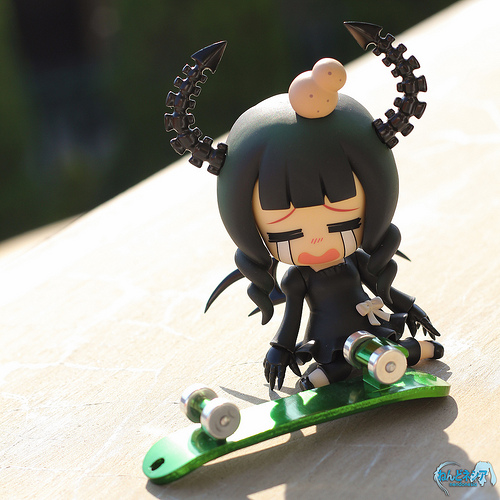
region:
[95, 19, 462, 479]
action figure with a green skateboard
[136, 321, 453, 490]
green skateboard with white wheels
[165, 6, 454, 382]
action figure with black horns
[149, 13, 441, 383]
action figure with black hair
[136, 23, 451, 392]
action figure with sad face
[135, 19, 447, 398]
action figure is crying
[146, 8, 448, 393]
action figure wearing all black with a single white bow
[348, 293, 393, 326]
white bow on action figure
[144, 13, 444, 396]
action figure wearing black gloves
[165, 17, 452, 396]
action figure with black hair and bangs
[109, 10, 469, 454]
plastic figurine on table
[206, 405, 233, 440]
wheel on the skateboard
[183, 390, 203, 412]
wheel on the skateboard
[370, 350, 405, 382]
wheel on the skateboard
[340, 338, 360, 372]
wheel on the skateboard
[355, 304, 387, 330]
bow on the figurine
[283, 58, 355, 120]
knot on the head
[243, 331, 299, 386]
hand of the figurine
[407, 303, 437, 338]
hand of the figurine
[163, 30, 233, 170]
horn of the figurine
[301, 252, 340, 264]
the lips are pink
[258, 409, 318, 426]
the skateboard is green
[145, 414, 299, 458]
the board is upside down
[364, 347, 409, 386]
the wheels are silver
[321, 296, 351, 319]
the shirt is black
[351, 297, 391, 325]
the bow is white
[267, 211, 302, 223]
the eyebrows are red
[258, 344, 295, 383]
the hands are black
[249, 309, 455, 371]
the firgure is sitting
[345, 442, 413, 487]
the table is tan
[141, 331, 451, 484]
Green toy skateboard.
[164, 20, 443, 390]
Doll with black devil horns.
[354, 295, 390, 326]
White bow on dolls dress.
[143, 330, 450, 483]
Green skateboard laying upside down.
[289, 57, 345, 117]
Tumor on girls head.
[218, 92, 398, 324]
The girl has black hair.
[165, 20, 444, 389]
The doll is crying.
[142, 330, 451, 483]
Green skateboard with silver wheels.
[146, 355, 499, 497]
The doll is casting a shadow.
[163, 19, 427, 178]
The doll has black horns.